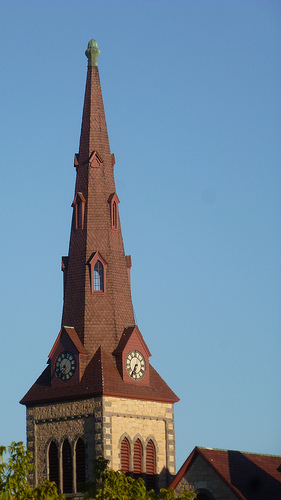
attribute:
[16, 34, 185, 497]
clock tower — brown, tan, red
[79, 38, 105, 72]
tip — blue, copper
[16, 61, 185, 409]
roof — brown, red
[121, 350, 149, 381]
clock — black, white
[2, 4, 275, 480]
part — blue, clear, cloudless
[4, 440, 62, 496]
plant — green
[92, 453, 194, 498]
leavesa — green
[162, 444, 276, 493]
edge — brown, red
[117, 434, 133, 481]
window — red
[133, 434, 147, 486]
window — red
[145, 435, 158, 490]
vent — red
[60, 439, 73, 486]
shutter — red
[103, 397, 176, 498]
wall — bricked, brown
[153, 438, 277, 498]
building — old